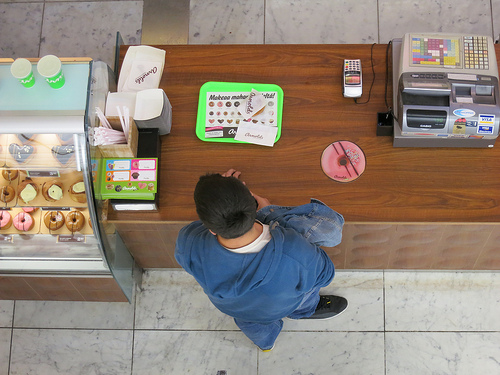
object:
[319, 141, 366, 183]
cd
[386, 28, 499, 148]
cash register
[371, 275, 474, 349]
floor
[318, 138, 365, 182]
donut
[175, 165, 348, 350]
man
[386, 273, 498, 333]
tile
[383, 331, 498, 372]
tile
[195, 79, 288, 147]
mat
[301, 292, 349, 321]
black shoes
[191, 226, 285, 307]
hood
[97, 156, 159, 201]
box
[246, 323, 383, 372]
tiles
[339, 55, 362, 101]
card reader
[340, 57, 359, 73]
keypad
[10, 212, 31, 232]
donut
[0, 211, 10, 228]
donut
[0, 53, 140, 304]
counter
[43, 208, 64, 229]
donut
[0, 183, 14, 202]
donut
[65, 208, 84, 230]
donut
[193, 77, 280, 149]
tray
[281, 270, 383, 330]
big tiles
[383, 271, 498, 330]
big tiles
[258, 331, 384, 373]
big tiles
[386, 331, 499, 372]
big tiles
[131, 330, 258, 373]
big tiles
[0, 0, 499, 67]
floor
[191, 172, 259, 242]
head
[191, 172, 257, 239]
hair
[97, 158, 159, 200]
flyers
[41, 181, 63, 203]
doughnuts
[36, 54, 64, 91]
cup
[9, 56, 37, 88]
cup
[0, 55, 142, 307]
case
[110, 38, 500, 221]
countertop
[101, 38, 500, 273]
checkout counter